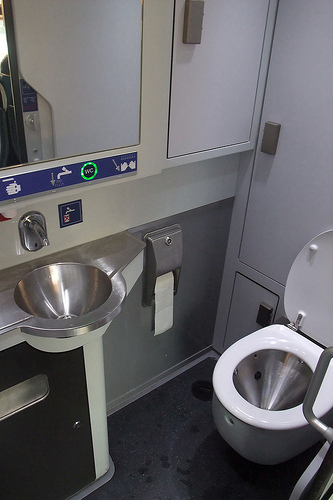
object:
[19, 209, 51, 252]
faucet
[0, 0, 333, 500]
scene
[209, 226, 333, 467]
toilet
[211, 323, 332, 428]
seat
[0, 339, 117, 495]
door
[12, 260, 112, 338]
silver sink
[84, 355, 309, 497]
floor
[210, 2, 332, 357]
cupboard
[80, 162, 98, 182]
button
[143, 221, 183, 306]
dispenser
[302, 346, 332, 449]
rail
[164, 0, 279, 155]
door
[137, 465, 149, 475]
water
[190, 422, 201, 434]
water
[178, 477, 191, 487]
water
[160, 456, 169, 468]
water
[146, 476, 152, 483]
water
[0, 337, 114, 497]
trashcan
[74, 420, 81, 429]
lock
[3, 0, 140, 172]
mirror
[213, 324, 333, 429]
top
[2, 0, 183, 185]
wall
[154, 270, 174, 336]
toilet paper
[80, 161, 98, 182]
light